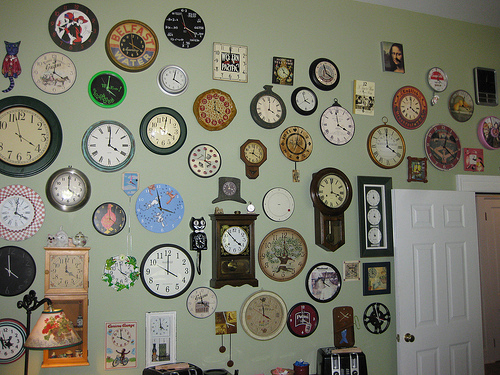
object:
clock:
[188, 215, 213, 276]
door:
[390, 184, 492, 375]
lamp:
[16, 290, 82, 374]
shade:
[21, 307, 88, 356]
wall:
[2, 2, 500, 375]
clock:
[86, 67, 128, 111]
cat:
[1, 36, 27, 94]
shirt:
[1, 54, 21, 76]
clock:
[156, 63, 189, 98]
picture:
[380, 36, 407, 75]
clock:
[190, 84, 235, 131]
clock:
[131, 184, 187, 241]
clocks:
[356, 170, 396, 258]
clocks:
[141, 308, 179, 368]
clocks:
[39, 235, 94, 371]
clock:
[160, 5, 206, 54]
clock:
[309, 168, 354, 253]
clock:
[426, 65, 448, 96]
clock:
[277, 126, 315, 166]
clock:
[1, 242, 38, 301]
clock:
[208, 41, 250, 84]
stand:
[17, 289, 52, 374]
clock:
[98, 250, 140, 293]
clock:
[45, 2, 101, 53]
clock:
[292, 86, 318, 119]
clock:
[103, 321, 141, 372]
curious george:
[115, 347, 132, 357]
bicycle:
[110, 354, 131, 366]